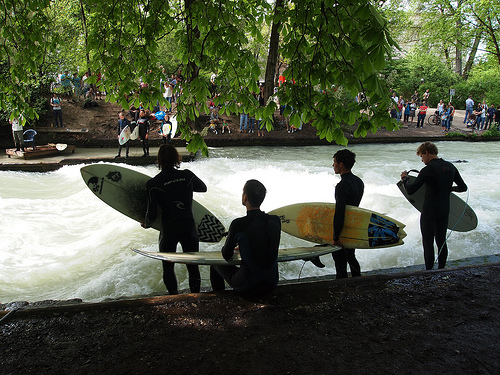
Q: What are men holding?
A: Surfboards.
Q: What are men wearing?
A: Wetsuits.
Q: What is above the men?
A: Tree branches.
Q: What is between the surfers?
A: River of water.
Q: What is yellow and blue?
A: Surfboard.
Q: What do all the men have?
A: Surfboards.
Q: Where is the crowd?
A: In background.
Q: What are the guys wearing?
A: Wetsuits.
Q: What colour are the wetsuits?
A: Black.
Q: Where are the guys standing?
A: Sides.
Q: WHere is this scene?
A: Water park.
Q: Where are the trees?
A: Background.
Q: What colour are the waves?
A: White.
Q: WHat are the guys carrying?
A: Surfboards.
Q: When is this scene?
A: Afternoon.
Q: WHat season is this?
A: Summer.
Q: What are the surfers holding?
A: Surfboards.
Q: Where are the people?
A: Other side of the bay.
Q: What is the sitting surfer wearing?
A: A black wetsuit.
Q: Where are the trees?
A: On the other side of the bay.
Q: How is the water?
A: White and frothy from the waves.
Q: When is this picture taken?
A: During daytime.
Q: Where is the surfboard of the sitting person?
A: On his lap.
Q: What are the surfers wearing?
A: Wet suits and shorts.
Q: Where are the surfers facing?
A: Towards the water with their backs towards the camera.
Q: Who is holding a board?
A: A man.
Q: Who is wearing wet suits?
A: The men.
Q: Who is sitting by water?
A: A man.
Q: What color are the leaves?
A: Green.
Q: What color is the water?
A: Blue.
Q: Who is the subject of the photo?
A: The people.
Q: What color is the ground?
A: Gray.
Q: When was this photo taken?
A: During the day.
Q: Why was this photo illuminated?
A: Sunlight.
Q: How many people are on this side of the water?
A: 4.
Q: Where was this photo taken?
A: Beside water.